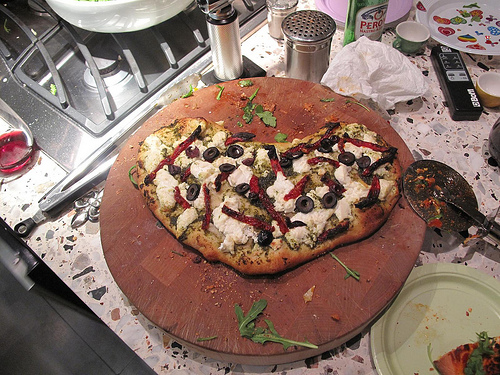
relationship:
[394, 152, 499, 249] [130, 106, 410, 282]
cutter for pizza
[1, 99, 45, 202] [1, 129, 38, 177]
glass for wine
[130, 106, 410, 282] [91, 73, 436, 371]
pizza on a board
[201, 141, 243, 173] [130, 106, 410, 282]
olives are on pizza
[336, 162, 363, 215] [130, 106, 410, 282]
cheese on pizza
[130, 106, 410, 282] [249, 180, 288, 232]
pizza with peppers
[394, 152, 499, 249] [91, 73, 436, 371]
cuter on board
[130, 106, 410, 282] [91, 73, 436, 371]
pizza on board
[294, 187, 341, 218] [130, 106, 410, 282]
olives are on pizza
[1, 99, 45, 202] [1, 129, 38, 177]
glass with red wine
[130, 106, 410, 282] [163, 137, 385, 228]
pizza has toppings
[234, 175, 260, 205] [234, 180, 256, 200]
olive color black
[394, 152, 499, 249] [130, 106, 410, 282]
cutter next to pizza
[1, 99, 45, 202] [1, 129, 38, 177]
glass with wine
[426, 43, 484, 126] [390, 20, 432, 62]
tv remote next to teacup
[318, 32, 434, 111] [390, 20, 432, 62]
napkin by teacup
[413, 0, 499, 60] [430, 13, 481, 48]
plate with hearts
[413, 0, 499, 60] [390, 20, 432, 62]
plate next to green cup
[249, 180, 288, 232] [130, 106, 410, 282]
red pepper on top pizza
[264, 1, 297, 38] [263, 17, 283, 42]
shaker with salt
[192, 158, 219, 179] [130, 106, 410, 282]
cheese on pizza